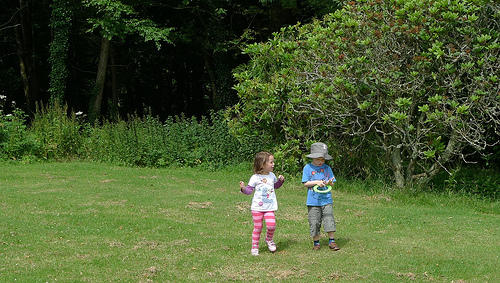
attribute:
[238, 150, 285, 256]
girl — walking, playing, small, standing, looking, little, excited, young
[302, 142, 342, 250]
boy — walking, playing, small, standing, little, young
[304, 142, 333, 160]
hat — grey, oversized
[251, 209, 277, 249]
tights — striped, pink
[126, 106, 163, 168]
plants — tall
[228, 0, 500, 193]
tree — lush, green, small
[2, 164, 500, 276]
grass — large, short, green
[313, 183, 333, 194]
toy — green, small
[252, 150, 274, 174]
hair — long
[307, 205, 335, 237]
shorts — grey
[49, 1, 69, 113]
tree trunk — covered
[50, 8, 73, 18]
vines — green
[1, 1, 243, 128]
forest — deep, dark, behind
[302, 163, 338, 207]
t-shirt — blue, pink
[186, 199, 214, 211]
pile of grass — dead, small, brown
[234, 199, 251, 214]
pile of grass — dead, small, brown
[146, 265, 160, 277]
pile of grass — dead, small, brown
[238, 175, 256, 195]
arms — moving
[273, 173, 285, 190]
arms — moving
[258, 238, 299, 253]
shadow — small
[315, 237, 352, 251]
shadow — small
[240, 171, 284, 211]
shirt — purple, white